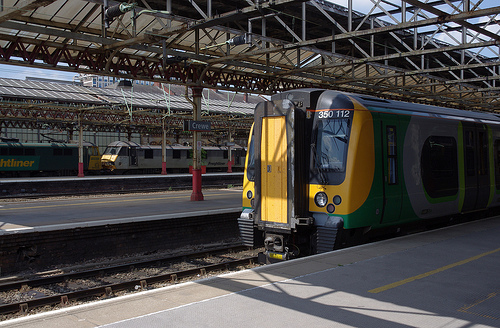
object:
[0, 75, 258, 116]
roof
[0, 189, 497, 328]
paved walkway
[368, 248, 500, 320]
lines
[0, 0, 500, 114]
girder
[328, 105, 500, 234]
green side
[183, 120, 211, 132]
blue sign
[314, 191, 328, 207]
headlight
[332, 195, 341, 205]
headlight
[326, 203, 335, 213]
headlight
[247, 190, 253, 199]
headlight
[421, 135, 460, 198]
window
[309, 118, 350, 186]
window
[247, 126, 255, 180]
window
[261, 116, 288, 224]
door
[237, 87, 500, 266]
train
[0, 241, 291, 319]
track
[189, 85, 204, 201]
metal pole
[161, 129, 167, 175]
metal pole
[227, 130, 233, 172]
metal pole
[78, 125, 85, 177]
metal pole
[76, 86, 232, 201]
steel poles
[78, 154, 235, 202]
red bottoms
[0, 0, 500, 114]
roof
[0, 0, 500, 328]
station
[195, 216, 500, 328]
shadow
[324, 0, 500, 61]
sky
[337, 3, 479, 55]
girders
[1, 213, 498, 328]
caution area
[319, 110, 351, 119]
identification number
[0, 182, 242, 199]
track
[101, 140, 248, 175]
train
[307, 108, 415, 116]
line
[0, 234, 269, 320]
gravel